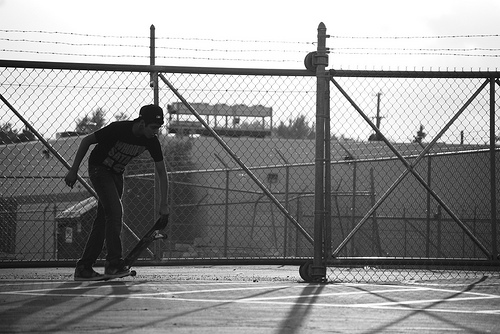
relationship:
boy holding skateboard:
[62, 102, 174, 284] [98, 212, 178, 282]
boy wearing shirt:
[62, 102, 174, 284] [91, 120, 164, 171]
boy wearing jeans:
[62, 102, 174, 284] [79, 162, 124, 262]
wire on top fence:
[2, 26, 497, 68] [2, 27, 498, 287]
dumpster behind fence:
[43, 192, 98, 261] [2, 48, 498, 275]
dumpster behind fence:
[43, 192, 98, 261] [293, 135, 486, 264]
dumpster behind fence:
[43, 192, 98, 261] [167, 154, 474, 257]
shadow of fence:
[0, 272, 497, 331] [2, 27, 498, 287]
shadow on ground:
[0, 272, 497, 331] [9, 257, 496, 332]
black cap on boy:
[132, 104, 162, 122] [62, 102, 174, 284]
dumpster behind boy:
[52, 195, 97, 261] [62, 102, 174, 284]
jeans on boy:
[77, 167, 124, 266] [62, 102, 174, 284]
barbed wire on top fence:
[2, 17, 304, 67] [2, 48, 498, 275]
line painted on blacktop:
[365, 289, 497, 310] [2, 267, 499, 333]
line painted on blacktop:
[239, 285, 422, 302] [2, 267, 499, 333]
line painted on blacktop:
[134, 281, 306, 297] [2, 267, 499, 333]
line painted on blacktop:
[20, 279, 130, 293] [2, 267, 499, 333]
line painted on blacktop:
[3, 289, 499, 318] [2, 267, 499, 333]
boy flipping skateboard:
[106, 107, 178, 183] [135, 235, 158, 255]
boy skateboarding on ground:
[62, 102, 174, 284] [1, 266, 498, 332]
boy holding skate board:
[62, 102, 174, 284] [118, 214, 168, 276]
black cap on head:
[132, 104, 164, 120] [132, 102, 165, 141]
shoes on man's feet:
[71, 257, 131, 284] [67, 264, 135, 280]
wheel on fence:
[297, 260, 317, 283] [2, 48, 498, 275]